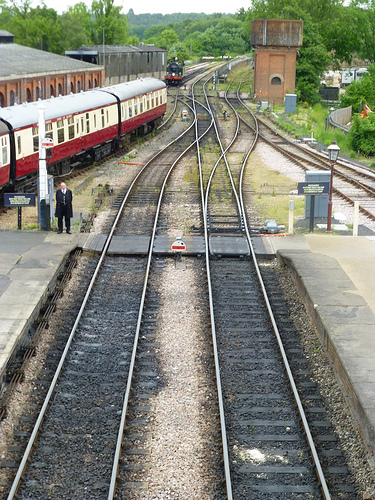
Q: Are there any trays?
A: No, there are no trays.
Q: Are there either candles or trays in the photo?
A: No, there are no trays or candles.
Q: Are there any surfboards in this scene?
A: No, there are no surfboards.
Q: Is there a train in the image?
A: Yes, there is a train.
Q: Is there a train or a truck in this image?
A: Yes, there is a train.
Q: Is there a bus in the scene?
A: No, there are no buses.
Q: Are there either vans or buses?
A: No, there are no buses or vans.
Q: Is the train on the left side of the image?
A: Yes, the train is on the left of the image.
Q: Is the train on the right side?
A: No, the train is on the left of the image.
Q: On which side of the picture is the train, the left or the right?
A: The train is on the left of the image.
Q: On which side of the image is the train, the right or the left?
A: The train is on the left of the image.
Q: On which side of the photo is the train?
A: The train is on the left of the image.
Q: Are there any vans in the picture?
A: No, there are no vans.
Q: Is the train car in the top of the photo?
A: Yes, the train car is in the top of the image.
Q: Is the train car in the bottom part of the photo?
A: No, the train car is in the top of the image.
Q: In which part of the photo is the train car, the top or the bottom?
A: The train car is in the top of the image.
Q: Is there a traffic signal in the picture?
A: No, there are no traffic lights.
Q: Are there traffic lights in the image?
A: No, there are no traffic lights.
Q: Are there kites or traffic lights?
A: No, there are no traffic lights or kites.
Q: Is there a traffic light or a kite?
A: No, there are no traffic lights or kites.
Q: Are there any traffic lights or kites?
A: No, there are no traffic lights or kites.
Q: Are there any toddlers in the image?
A: No, there are no toddlers.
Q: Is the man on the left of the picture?
A: Yes, the man is on the left of the image.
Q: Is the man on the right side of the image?
A: No, the man is on the left of the image.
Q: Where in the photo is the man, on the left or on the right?
A: The man is on the left of the image.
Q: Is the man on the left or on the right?
A: The man is on the left of the image.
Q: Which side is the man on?
A: The man is on the left of the image.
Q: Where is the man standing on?
A: The man is standing on the pavement.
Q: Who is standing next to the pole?
A: The man is standing next to the pole.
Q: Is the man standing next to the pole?
A: Yes, the man is standing next to the pole.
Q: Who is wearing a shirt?
A: The man is wearing a shirt.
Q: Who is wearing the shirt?
A: The man is wearing a shirt.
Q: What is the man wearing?
A: The man is wearing a shirt.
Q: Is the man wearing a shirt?
A: Yes, the man is wearing a shirt.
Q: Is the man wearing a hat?
A: No, the man is wearing a shirt.